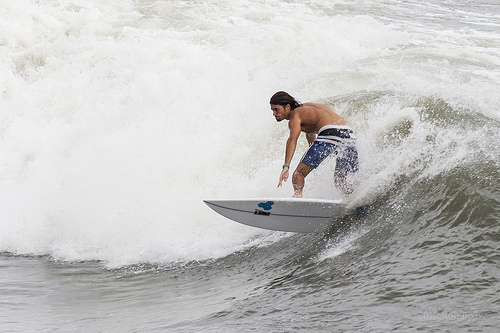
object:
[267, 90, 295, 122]
head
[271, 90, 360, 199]
surfer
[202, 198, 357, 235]
surf board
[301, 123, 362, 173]
shorts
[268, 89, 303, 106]
hair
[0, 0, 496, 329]
water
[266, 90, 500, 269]
wave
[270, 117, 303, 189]
arm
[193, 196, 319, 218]
tip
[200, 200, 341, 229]
bottom